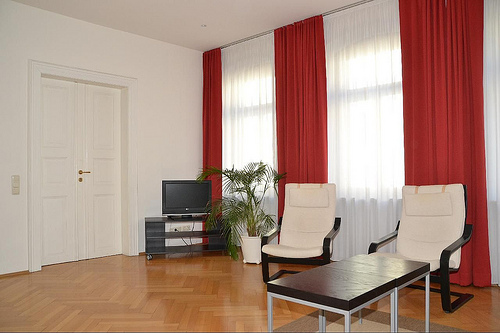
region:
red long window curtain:
[203, 50, 223, 245]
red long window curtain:
[278, 23, 328, 184]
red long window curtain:
[414, 5, 475, 186]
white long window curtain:
[223, 53, 274, 169]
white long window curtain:
[324, 13, 401, 168]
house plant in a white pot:
[213, 158, 277, 274]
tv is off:
[161, 175, 216, 218]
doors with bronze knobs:
[33, 67, 140, 278]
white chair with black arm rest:
[260, 170, 330, 266]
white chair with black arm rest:
[378, 184, 467, 284]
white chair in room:
[382, 176, 464, 280]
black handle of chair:
[431, 233, 481, 325]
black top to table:
[285, 245, 419, 305]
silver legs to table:
[380, 273, 440, 321]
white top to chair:
[251, 186, 342, 267]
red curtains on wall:
[271, 13, 331, 178]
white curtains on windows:
[314, 23, 399, 191]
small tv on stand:
[165, 175, 220, 217]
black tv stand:
[144, 205, 238, 255]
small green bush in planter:
[228, 152, 273, 243]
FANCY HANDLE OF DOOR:
[71, 168, 94, 186]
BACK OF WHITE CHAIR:
[402, 185, 464, 220]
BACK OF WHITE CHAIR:
[282, 183, 336, 218]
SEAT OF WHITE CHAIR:
[269, 242, 311, 256]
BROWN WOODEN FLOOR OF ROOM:
[92, 293, 192, 325]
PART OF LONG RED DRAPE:
[202, 60, 220, 165]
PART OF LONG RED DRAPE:
[280, 40, 310, 118]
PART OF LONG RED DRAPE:
[412, 79, 446, 174]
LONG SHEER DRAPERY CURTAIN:
[335, 25, 375, 138]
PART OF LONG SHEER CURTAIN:
[239, 55, 270, 88]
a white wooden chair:
[258, 180, 343, 288]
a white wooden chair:
[365, 182, 470, 314]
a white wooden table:
[263, 251, 430, 331]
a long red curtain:
[272, 16, 327, 261]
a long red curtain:
[396, 0, 486, 290]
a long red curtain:
[198, 48, 226, 255]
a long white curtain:
[218, 30, 275, 252]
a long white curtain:
[320, 2, 405, 280]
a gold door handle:
[77, 164, 92, 176]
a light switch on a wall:
[8, 171, 22, 196]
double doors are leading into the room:
[28, 59, 142, 267]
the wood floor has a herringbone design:
[2, 241, 498, 329]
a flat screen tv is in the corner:
[156, 176, 214, 219]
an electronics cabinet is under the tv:
[141, 213, 236, 260]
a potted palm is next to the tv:
[203, 161, 280, 269]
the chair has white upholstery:
[260, 177, 342, 286]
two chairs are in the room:
[258, 178, 478, 318]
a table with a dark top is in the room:
[266, 248, 431, 331]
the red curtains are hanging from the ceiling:
[199, 4, 494, 291]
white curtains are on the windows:
[221, 2, 404, 276]